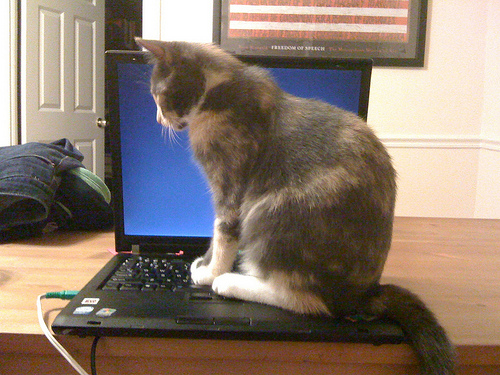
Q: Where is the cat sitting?
A: On a laptop.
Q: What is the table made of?
A: Wood.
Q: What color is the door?
A: White.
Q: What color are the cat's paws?
A: White.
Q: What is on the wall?
A: An American Flag poster.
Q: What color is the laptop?
A: Black.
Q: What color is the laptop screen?
A: Blue.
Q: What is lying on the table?
A: Clothing.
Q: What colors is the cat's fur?
A: Gray and orange.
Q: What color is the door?
A: White.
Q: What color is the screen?
A: Blue.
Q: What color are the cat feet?
A: White.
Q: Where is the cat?
A: On computer.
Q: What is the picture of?
A: USA flag.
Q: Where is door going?
A: Out room.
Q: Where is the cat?
A: On laptop.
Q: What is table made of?
A: Wood.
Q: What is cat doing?
A: Sitting.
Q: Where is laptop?
A: On table.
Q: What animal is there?
A: Cat.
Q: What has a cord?
A: Laptop.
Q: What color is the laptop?
A: Black.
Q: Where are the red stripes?
A: Wall art.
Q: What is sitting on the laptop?
A: Cat.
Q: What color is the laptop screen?
A: Blue.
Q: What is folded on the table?
A: Clothes.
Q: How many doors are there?
A: 1.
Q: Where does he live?
A: With me.